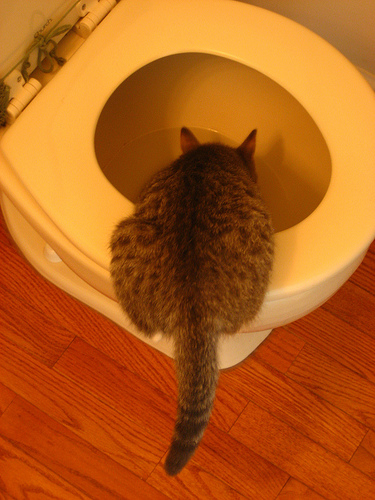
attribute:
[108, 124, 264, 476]
cat — visable, gray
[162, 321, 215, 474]
tail — partial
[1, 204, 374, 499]
floor — wooden, partial, patterned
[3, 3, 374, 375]
toilet — white, partial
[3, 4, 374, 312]
seat — rimmed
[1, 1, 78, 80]
toilet seat cover — back